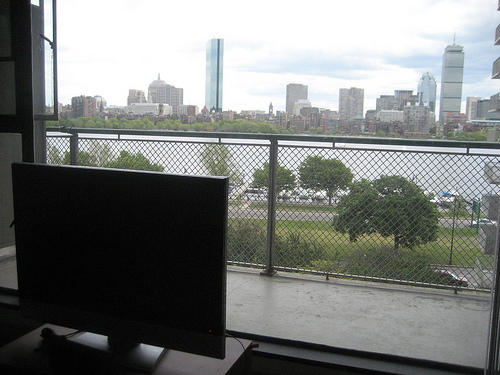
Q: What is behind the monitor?
A: A fence.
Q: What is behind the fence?
A: Grassy field.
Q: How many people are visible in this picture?
A: Zero.